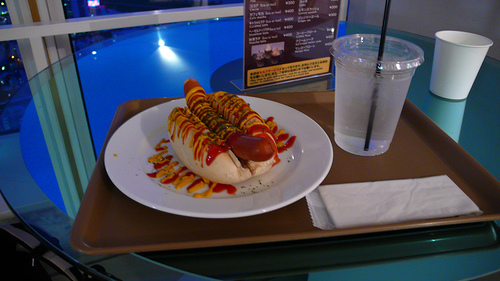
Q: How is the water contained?
A: Plastic glass.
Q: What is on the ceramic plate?
A: Hot dog.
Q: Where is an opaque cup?
A: Upper right corner.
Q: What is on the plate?
A: A hotdog.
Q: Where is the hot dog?
A: On the plate.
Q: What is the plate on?
A: A tray.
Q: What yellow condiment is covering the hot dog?
A: Mustard.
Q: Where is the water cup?
A: On the tray.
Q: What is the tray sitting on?
A: A table.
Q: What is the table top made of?
A: Glass.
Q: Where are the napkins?
A: On a tray.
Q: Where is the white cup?
A: On the table.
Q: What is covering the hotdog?
A: Condiments.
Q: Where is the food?
A: On a white plate.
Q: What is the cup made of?
A: Plastic.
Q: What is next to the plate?
A: A napkin.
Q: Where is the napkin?
A: On the brown tray.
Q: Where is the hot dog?
A: On the plate.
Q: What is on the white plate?
A: A hot dog.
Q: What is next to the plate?
A: A glass of water.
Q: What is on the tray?
A: A plate, glass, and napkin.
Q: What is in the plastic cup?
A: A straw.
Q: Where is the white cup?
A: Next to the tray.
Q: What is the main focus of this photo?
A: A hot dog with ketchup and bright yellow mustard.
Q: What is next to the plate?
A: A beverage in clear plastic cup with straw.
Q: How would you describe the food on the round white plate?
A: A hotdog in a bun.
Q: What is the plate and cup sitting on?
A: A rectangular brown food serving tray.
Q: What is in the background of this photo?
A: A menu in a vertical plastic holder.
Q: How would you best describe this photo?
A: A hot dog and beverage meal.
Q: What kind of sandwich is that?
A: It is a hotdog sandwich.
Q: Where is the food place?
A: It is on the glass table.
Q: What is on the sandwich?
A: It is hot dog with sauce.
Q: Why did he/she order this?
A: Because he/she is craving for hot dog.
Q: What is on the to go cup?
A: It is a cold water.